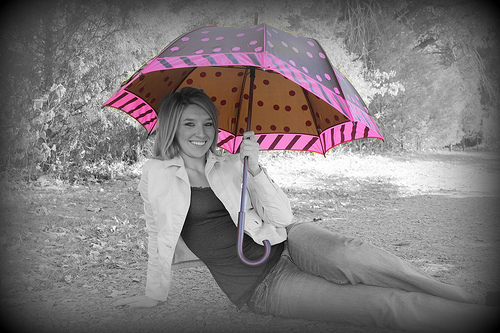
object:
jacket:
[139, 153, 293, 301]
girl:
[110, 86, 500, 329]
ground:
[0, 154, 499, 333]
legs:
[286, 222, 486, 306]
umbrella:
[104, 24, 387, 262]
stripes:
[285, 135, 301, 149]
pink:
[273, 135, 295, 150]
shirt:
[180, 186, 282, 310]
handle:
[236, 212, 272, 268]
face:
[178, 105, 214, 157]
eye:
[185, 122, 194, 126]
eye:
[205, 122, 212, 125]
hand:
[240, 131, 260, 170]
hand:
[110, 296, 158, 308]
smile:
[187, 139, 207, 148]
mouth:
[189, 140, 207, 146]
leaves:
[34, 202, 143, 295]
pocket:
[246, 213, 276, 237]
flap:
[246, 213, 262, 230]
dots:
[289, 60, 295, 67]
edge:
[265, 54, 355, 122]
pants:
[246, 221, 500, 332]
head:
[175, 87, 219, 157]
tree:
[0, 0, 113, 177]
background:
[0, 0, 499, 198]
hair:
[154, 86, 219, 159]